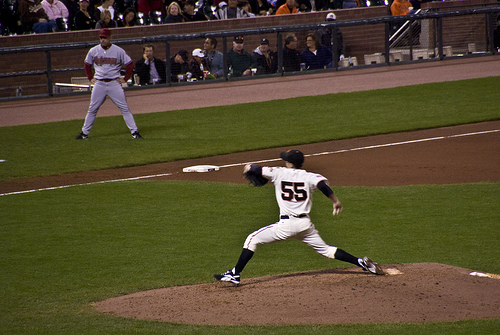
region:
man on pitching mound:
[205, 141, 397, 296]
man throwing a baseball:
[203, 137, 390, 292]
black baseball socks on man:
[333, 246, 360, 267]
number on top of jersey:
[272, 174, 310, 210]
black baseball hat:
[274, 145, 310, 166]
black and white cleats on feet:
[210, 265, 247, 285]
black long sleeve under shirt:
[312, 174, 335, 196]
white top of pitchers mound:
[382, 253, 403, 284]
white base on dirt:
[182, 157, 222, 178]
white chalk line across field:
[371, 120, 461, 158]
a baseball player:
[218, 149, 385, 284]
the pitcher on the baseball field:
[211, 150, 383, 277]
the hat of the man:
[273, 151, 307, 165]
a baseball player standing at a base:
[80, 25, 145, 145]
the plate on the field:
[181, 162, 222, 172]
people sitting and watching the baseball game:
[3, 0, 437, 81]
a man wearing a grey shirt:
[201, 36, 223, 75]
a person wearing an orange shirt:
[275, 1, 302, 13]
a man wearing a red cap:
[83, 31, 144, 140]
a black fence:
[11, 15, 493, 88]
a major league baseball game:
[18, 8, 470, 313]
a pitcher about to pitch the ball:
[194, 142, 410, 291]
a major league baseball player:
[210, 143, 400, 293]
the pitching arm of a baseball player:
[310, 171, 345, 216]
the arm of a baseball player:
[241, 158, 273, 195]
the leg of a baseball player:
[305, 225, 380, 276]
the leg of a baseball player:
[206, 218, 288, 288]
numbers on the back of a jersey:
[277, 177, 307, 202]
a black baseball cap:
[276, 145, 309, 171]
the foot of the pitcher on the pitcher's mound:
[351, 243, 404, 282]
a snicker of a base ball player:
[216, 270, 244, 285]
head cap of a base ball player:
[280, 150, 305, 166]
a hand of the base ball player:
[321, 183, 343, 216]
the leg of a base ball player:
[306, 230, 394, 273]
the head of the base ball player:
[277, 145, 307, 166]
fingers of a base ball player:
[331, 205, 336, 215]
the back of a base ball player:
[277, 171, 312, 211]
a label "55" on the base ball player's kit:
[277, 176, 312, 204]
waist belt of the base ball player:
[278, 213, 293, 219]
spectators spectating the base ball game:
[143, 44, 327, 79]